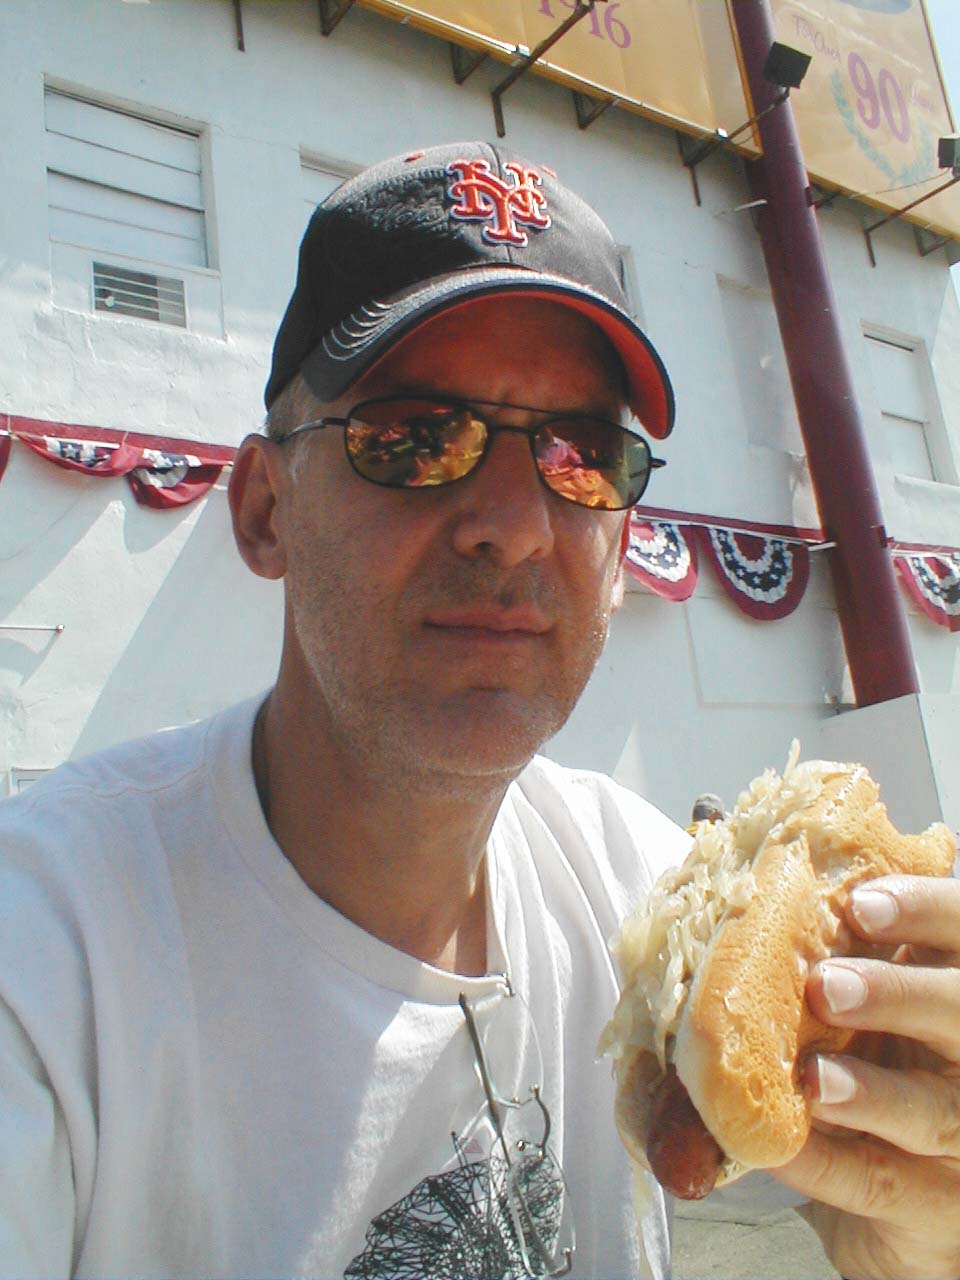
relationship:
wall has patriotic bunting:
[6, 4, 949, 859] [0, 403, 820, 622]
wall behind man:
[0, 0, 959, 1221] [5, 108, 902, 1277]